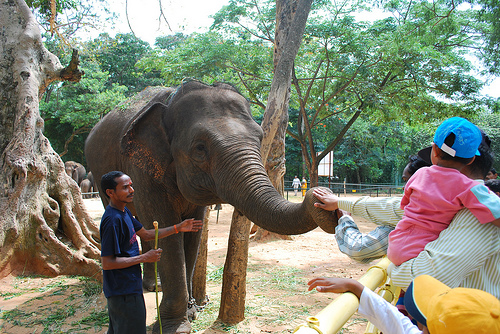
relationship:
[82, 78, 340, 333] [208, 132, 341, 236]
elephant extending trunk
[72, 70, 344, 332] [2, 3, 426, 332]
elephant in zoo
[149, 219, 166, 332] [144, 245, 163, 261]
stick in hand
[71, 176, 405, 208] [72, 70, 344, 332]
fence enclosing elephant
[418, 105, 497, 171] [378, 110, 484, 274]
baseball cap enclosing baby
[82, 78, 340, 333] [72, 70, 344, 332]
elephant of elephant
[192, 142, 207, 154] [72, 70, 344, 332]
eye of elephant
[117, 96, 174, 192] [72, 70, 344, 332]
ear of elephant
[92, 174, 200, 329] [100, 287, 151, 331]
man wearing pants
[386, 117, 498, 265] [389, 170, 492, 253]
baby wearing shirt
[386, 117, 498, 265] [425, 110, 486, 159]
baby wearing hat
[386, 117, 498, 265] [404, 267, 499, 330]
baby wearing hat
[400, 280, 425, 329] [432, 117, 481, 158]
stripe on baseball cap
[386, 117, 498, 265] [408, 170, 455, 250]
baby wearing outfit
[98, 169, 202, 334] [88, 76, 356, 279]
man standing next to elephant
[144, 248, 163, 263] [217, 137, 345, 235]
hand on trunk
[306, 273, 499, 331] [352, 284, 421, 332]
child wearing shirt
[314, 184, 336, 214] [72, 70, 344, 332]
hand touching elephant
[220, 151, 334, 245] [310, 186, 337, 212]
trunk touching hand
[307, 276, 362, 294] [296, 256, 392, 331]
man's hand on fence